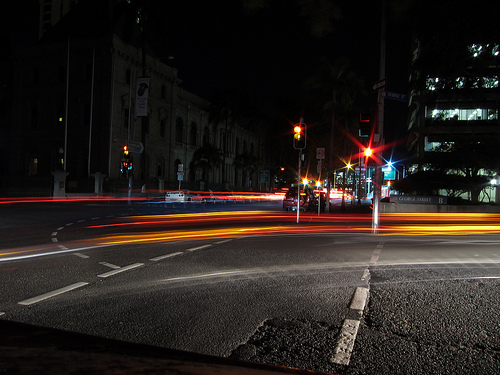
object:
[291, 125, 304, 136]
light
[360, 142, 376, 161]
light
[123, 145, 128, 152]
light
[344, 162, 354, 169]
light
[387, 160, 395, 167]
light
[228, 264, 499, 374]
patched pavement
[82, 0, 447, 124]
sky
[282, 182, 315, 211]
car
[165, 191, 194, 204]
car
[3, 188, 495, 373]
road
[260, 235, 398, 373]
markedtarmac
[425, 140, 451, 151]
window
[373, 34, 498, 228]
building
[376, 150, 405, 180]
burst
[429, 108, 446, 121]
window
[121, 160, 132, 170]
signal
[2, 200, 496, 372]
street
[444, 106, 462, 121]
window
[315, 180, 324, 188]
street light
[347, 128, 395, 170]
star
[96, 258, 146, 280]
marking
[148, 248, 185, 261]
marking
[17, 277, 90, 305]
marking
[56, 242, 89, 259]
marking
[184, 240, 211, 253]
marking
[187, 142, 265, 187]
trees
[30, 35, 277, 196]
building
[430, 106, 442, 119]
glass window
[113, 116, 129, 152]
wall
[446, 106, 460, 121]
light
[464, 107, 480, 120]
light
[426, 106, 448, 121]
light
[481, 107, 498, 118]
window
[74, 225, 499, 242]
light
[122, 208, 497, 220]
light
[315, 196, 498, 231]
sidewalk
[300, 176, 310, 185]
street light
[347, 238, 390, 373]
line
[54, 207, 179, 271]
line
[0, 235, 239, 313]
line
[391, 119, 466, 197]
tree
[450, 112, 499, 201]
tree